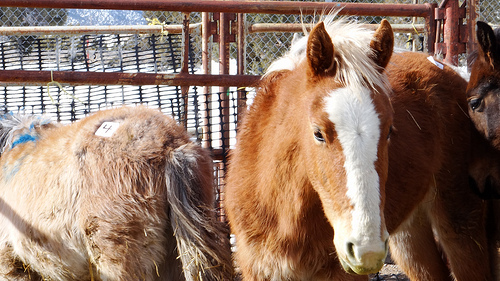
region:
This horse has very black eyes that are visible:
[311, 107, 387, 188]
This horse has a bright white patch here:
[347, 114, 379, 210]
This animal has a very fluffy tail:
[172, 158, 208, 276]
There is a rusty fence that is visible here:
[163, 49, 193, 95]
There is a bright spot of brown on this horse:
[419, 103, 441, 171]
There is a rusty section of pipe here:
[152, 25, 164, 41]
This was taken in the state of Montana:
[81, 22, 371, 229]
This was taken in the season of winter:
[71, 25, 358, 252]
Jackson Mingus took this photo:
[88, 27, 379, 279]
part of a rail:
[215, 85, 229, 99]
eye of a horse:
[314, 140, 334, 187]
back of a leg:
[132, 216, 161, 251]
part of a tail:
[218, 206, 227, 243]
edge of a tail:
[157, 163, 210, 263]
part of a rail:
[176, 70, 187, 78]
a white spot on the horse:
[325, 75, 390, 245]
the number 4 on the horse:
[94, 116, 114, 138]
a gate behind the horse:
[0, 1, 475, 164]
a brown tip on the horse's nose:
[349, 243, 386, 273]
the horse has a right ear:
[305, 17, 336, 70]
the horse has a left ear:
[374, 9, 394, 66]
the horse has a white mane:
[267, 14, 383, 92]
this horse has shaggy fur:
[0, 97, 209, 260]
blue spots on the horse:
[0, 112, 49, 178]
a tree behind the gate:
[4, 0, 66, 62]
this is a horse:
[254, 25, 431, 280]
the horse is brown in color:
[404, 96, 458, 204]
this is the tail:
[160, 162, 197, 279]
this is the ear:
[301, 16, 328, 73]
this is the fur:
[342, 40, 373, 69]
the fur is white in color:
[338, 24, 362, 71]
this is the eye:
[308, 115, 322, 141]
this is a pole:
[93, 64, 190, 100]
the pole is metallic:
[132, 67, 173, 87]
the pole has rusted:
[104, 65, 136, 86]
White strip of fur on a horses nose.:
[325, 84, 382, 251]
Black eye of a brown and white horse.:
[313, 127, 325, 142]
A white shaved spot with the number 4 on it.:
[93, 119, 118, 139]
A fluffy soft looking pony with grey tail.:
[1, 103, 231, 280]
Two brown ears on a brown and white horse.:
[305, 18, 394, 70]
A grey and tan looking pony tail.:
[164, 143, 232, 279]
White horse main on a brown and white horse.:
[264, 5, 396, 92]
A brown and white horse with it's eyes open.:
[223, 15, 491, 280]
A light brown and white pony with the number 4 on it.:
[0, 101, 234, 279]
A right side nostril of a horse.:
[346, 238, 358, 260]